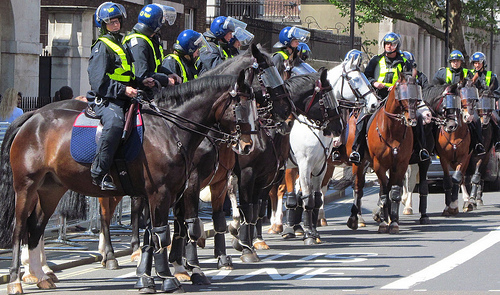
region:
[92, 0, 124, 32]
a blue helmet on a man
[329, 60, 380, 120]
the head of a white horse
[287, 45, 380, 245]
a white horse standing in a line-up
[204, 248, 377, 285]
white paint on the street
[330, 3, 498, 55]
a tree in the background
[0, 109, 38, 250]
a black tail of a horse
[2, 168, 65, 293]
two legs on a horse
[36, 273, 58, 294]
the hoof of a horse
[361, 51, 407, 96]
the jacket of a man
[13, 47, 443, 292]
a large group of beautiful horses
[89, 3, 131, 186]
police officer on horse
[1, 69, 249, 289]
horse standing still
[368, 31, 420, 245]
man riding a horse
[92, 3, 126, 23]
blue helmet on man's head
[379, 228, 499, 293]
white line painted on street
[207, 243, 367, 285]
white lettering painted on street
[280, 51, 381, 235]
white horse in between brown horses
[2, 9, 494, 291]
policemen sitting on horses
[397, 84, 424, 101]
shield on the horse's eyes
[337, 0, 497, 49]
tree in the background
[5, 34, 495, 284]
large group of horses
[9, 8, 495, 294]
police officers on horses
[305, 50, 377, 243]
white horse in middle of group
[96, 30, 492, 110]
neon stripes on police officers' vests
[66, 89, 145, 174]
saddle of first horse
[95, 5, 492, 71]
blue helmets of police officers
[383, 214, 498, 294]
white line painted on road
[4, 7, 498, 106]
buildings behind police officers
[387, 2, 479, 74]
tree behind officers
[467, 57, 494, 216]
last officer and horse in line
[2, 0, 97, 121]
white columns behind horses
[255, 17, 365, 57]
low black structure behind officers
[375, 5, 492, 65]
split tree in front of white building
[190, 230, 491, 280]
white lettering and line on street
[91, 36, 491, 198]
white horse in middle of dark horses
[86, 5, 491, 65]
officers wearing blue helmets with visors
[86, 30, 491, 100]
officers wearing reflective yellow stripes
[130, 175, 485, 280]
horses wearing protective gear on front legs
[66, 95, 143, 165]
gray, red and blue padding under saddle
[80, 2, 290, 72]
men on horses have blue helmets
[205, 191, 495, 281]
white paint on grey street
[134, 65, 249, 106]
horse in front has brown mane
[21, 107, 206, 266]
horse in front is brown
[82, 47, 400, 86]
men are wearing blue jackets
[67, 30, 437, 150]
blue jackets have yellow reflective stripes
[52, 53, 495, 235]
men are on horses in cordon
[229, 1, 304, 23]
black railing above men and horses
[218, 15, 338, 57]
face guards on front of helmets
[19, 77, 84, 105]
people walking on sidewalk behind horses